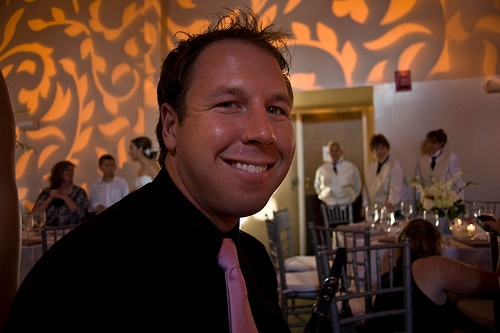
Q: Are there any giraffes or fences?
A: No, there are no fences or giraffes.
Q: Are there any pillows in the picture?
A: No, there are no pillows.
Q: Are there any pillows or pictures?
A: No, there are no pillows or pictures.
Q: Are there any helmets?
A: No, there are no helmets.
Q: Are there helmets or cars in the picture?
A: No, there are no helmets or cars.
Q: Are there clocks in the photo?
A: No, there are no clocks.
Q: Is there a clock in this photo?
A: No, there are no clocks.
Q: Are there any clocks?
A: No, there are no clocks.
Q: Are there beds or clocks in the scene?
A: No, there are no clocks or beds.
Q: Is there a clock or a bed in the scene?
A: No, there are no clocks or beds.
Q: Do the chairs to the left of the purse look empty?
A: Yes, the chairs are empty.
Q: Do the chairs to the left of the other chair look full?
A: No, the chairs are empty.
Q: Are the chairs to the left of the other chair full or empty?
A: The chairs are empty.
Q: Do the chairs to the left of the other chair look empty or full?
A: The chairs are empty.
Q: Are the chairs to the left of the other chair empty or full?
A: The chairs are empty.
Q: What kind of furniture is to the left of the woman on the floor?
A: The pieces of furniture are chairs.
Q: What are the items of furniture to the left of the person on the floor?
A: The pieces of furniture are chairs.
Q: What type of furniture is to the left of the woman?
A: The pieces of furniture are chairs.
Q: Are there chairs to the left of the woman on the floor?
A: Yes, there are chairs to the left of the woman.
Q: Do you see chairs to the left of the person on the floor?
A: Yes, there are chairs to the left of the woman.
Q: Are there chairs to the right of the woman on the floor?
A: No, the chairs are to the left of the woman.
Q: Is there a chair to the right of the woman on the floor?
A: No, the chairs are to the left of the woman.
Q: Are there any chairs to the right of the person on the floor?
A: No, the chairs are to the left of the woman.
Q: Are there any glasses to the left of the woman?
A: No, there are chairs to the left of the woman.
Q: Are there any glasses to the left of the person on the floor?
A: No, there are chairs to the left of the woman.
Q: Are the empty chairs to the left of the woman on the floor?
A: Yes, the chairs are to the left of the woman.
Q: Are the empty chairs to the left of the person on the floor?
A: Yes, the chairs are to the left of the woman.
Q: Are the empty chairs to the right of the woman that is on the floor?
A: No, the chairs are to the left of the woman.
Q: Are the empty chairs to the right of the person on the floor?
A: No, the chairs are to the left of the woman.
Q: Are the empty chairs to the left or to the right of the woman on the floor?
A: The chairs are to the left of the woman.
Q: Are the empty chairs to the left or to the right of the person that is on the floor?
A: The chairs are to the left of the woman.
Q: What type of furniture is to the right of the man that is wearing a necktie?
A: The pieces of furniture are chairs.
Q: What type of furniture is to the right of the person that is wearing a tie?
A: The pieces of furniture are chairs.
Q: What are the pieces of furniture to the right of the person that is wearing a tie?
A: The pieces of furniture are chairs.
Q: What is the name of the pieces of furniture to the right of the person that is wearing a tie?
A: The pieces of furniture are chairs.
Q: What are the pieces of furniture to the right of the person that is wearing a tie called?
A: The pieces of furniture are chairs.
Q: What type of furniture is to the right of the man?
A: The pieces of furniture are chairs.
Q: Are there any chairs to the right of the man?
A: Yes, there are chairs to the right of the man.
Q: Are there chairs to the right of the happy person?
A: Yes, there are chairs to the right of the man.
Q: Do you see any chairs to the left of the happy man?
A: No, the chairs are to the right of the man.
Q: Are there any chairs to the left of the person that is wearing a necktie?
A: No, the chairs are to the right of the man.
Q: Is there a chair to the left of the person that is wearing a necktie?
A: No, the chairs are to the right of the man.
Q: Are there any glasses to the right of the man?
A: No, there are chairs to the right of the man.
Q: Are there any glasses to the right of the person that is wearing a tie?
A: No, there are chairs to the right of the man.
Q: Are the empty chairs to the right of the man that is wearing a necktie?
A: Yes, the chairs are to the right of the man.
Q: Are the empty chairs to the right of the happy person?
A: Yes, the chairs are to the right of the man.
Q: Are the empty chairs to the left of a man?
A: No, the chairs are to the right of a man.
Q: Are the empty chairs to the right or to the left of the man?
A: The chairs are to the right of the man.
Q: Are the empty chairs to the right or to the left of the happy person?
A: The chairs are to the right of the man.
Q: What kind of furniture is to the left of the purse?
A: The pieces of furniture are chairs.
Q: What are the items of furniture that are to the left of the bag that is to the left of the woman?
A: The pieces of furniture are chairs.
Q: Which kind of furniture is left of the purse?
A: The pieces of furniture are chairs.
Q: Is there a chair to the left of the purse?
A: Yes, there are chairs to the left of the purse.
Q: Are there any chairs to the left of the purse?
A: Yes, there are chairs to the left of the purse.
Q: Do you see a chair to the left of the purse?
A: Yes, there are chairs to the left of the purse.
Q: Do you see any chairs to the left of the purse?
A: Yes, there are chairs to the left of the purse.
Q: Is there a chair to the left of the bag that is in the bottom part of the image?
A: Yes, there are chairs to the left of the purse.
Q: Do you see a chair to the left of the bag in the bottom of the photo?
A: Yes, there are chairs to the left of the purse.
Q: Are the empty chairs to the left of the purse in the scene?
A: Yes, the chairs are to the left of the purse.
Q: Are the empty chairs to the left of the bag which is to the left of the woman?
A: Yes, the chairs are to the left of the purse.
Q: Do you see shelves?
A: No, there are no shelves.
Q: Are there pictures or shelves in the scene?
A: No, there are no shelves or pictures.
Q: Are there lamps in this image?
A: No, there are no lamps.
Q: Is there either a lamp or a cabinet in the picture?
A: No, there are no lamps or cabinets.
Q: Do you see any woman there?
A: Yes, there is a woman.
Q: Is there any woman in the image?
A: Yes, there is a woman.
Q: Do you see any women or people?
A: Yes, there is a woman.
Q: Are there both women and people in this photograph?
A: Yes, there are both a woman and a person.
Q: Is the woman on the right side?
A: Yes, the woman is on the right of the image.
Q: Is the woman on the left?
A: No, the woman is on the right of the image.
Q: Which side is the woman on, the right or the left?
A: The woman is on the right of the image.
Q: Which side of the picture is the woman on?
A: The woman is on the right of the image.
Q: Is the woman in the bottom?
A: Yes, the woman is in the bottom of the image.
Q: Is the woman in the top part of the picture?
A: No, the woman is in the bottom of the image.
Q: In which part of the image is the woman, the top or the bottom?
A: The woman is in the bottom of the image.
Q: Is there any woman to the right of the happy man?
A: Yes, there is a woman to the right of the man.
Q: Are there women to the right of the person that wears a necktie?
A: Yes, there is a woman to the right of the man.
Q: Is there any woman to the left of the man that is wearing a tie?
A: No, the woman is to the right of the man.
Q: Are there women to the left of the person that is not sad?
A: No, the woman is to the right of the man.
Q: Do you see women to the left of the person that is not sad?
A: No, the woman is to the right of the man.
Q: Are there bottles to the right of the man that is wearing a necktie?
A: No, there is a woman to the right of the man.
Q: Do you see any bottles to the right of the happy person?
A: No, there is a woman to the right of the man.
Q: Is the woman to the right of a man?
A: Yes, the woman is to the right of a man.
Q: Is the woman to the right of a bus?
A: No, the woman is to the right of a man.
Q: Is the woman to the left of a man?
A: No, the woman is to the right of a man.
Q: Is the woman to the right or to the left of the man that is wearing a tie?
A: The woman is to the right of the man.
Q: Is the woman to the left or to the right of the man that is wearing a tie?
A: The woman is to the right of the man.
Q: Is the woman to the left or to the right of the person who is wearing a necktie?
A: The woman is to the right of the man.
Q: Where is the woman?
A: The woman is on the floor.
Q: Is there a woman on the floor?
A: Yes, there is a woman on the floor.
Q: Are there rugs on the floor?
A: No, there is a woman on the floor.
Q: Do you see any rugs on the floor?
A: No, there is a woman on the floor.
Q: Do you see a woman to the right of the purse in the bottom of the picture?
A: Yes, there is a woman to the right of the purse.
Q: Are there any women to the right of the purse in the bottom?
A: Yes, there is a woman to the right of the purse.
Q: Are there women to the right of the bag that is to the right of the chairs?
A: Yes, there is a woman to the right of the purse.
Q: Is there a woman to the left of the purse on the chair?
A: No, the woman is to the right of the purse.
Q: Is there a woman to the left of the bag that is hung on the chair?
A: No, the woman is to the right of the purse.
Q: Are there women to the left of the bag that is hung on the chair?
A: No, the woman is to the right of the purse.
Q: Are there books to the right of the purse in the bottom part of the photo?
A: No, there is a woman to the right of the purse.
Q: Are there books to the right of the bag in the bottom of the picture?
A: No, there is a woman to the right of the purse.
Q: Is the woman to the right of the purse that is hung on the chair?
A: Yes, the woman is to the right of the purse.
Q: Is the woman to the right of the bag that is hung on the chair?
A: Yes, the woman is to the right of the purse.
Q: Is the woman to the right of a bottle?
A: No, the woman is to the right of the purse.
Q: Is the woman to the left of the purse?
A: No, the woman is to the right of the purse.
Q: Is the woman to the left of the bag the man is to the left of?
A: No, the woman is to the right of the purse.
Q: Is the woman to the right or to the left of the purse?
A: The woman is to the right of the purse.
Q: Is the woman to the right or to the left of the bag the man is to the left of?
A: The woman is to the right of the purse.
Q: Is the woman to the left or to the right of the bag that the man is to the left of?
A: The woman is to the right of the purse.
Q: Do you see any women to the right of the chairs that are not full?
A: Yes, there is a woman to the right of the chairs.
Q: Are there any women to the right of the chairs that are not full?
A: Yes, there is a woman to the right of the chairs.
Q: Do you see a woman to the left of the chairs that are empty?
A: No, the woman is to the right of the chairs.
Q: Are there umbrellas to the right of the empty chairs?
A: No, there is a woman to the right of the chairs.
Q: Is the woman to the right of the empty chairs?
A: Yes, the woman is to the right of the chairs.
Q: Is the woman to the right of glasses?
A: No, the woman is to the right of the chairs.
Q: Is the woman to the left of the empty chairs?
A: No, the woman is to the right of the chairs.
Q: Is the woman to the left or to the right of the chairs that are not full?
A: The woman is to the right of the chairs.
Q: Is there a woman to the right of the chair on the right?
A: Yes, there is a woman to the right of the chair.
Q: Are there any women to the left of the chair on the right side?
A: No, the woman is to the right of the chair.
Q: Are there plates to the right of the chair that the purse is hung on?
A: No, there is a woman to the right of the chair.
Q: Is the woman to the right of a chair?
A: Yes, the woman is to the right of a chair.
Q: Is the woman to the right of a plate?
A: No, the woman is to the right of a chair.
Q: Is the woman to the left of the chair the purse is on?
A: No, the woman is to the right of the chair.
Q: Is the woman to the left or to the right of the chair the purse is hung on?
A: The woman is to the right of the chair.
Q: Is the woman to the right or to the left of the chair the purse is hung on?
A: The woman is to the right of the chair.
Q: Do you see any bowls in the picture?
A: No, there are no bowls.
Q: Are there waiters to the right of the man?
A: Yes, there is a waiter to the right of the man.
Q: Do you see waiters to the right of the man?
A: Yes, there is a waiter to the right of the man.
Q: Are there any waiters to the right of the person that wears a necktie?
A: Yes, there is a waiter to the right of the man.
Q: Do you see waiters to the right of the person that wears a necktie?
A: Yes, there is a waiter to the right of the man.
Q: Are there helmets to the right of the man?
A: No, there is a waiter to the right of the man.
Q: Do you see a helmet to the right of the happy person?
A: No, there is a waiter to the right of the man.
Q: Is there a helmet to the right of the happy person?
A: No, there is a waiter to the right of the man.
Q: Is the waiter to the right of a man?
A: Yes, the waiter is to the right of a man.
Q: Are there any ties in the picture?
A: Yes, there is a tie.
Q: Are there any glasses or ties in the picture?
A: Yes, there is a tie.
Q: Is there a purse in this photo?
A: Yes, there is a purse.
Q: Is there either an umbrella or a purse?
A: Yes, there is a purse.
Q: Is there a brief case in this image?
A: No, there are no briefcases.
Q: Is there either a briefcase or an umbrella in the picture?
A: No, there are no briefcases or umbrellas.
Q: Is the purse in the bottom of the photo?
A: Yes, the purse is in the bottom of the image.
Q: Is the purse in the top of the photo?
A: No, the purse is in the bottom of the image.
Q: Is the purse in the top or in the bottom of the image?
A: The purse is in the bottom of the image.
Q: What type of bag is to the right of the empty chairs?
A: The bag is a purse.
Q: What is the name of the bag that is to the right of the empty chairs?
A: The bag is a purse.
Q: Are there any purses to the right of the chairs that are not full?
A: Yes, there is a purse to the right of the chairs.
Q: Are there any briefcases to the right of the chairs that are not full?
A: No, there is a purse to the right of the chairs.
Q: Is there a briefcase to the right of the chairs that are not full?
A: No, there is a purse to the right of the chairs.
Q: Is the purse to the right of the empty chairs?
A: Yes, the purse is to the right of the chairs.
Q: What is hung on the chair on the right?
A: The purse is hung on the chair.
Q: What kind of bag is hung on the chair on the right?
A: The bag is a purse.